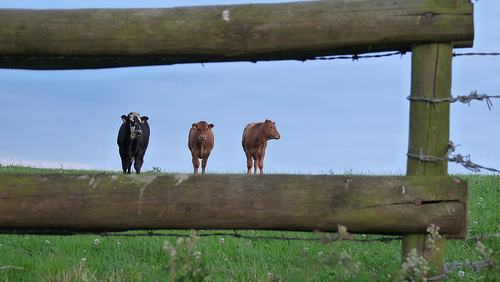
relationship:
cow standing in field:
[241, 118, 280, 175] [3, 110, 427, 275]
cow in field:
[116, 111, 151, 175] [33, 82, 499, 267]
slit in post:
[390, 190, 460, 209] [5, 165, 468, 234]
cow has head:
[116, 111, 151, 175] [122, 110, 150, 140]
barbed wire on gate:
[166, 37, 420, 67] [7, 3, 480, 264]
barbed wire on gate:
[86, 225, 406, 244] [7, 3, 480, 264]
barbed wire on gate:
[448, 46, 498, 57] [7, 3, 480, 264]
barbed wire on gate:
[406, 87, 498, 105] [7, 3, 480, 264]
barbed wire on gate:
[405, 149, 499, 177] [7, 3, 480, 264]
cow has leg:
[186, 120, 215, 175] [199, 154, 209, 174]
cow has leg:
[186, 120, 215, 175] [190, 154, 200, 173]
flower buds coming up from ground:
[1, 174, 499, 280] [0, 164, 498, 281]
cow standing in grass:
[116, 111, 151, 175] [0, 166, 499, 280]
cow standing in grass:
[186, 120, 215, 175] [0, 166, 499, 280]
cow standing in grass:
[241, 118, 280, 175] [0, 166, 499, 280]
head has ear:
[191, 120, 215, 141] [191, 122, 199, 132]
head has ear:
[191, 120, 215, 141] [207, 124, 214, 131]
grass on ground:
[0, 166, 499, 280] [0, 164, 498, 281]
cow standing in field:
[241, 118, 280, 175] [0, 163, 499, 282]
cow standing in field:
[114, 108, 150, 171] [0, 163, 499, 282]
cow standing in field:
[186, 120, 215, 175] [0, 163, 499, 282]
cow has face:
[116, 111, 151, 175] [126, 114, 143, 136]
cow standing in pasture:
[241, 118, 280, 175] [7, 236, 403, 280]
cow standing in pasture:
[186, 120, 215, 175] [7, 236, 403, 280]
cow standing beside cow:
[186, 120, 215, 175] [243, 116, 283, 172]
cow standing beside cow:
[186, 120, 215, 175] [114, 108, 150, 171]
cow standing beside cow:
[114, 111, 169, 178] [187, 120, 227, 174]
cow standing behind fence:
[116, 111, 151, 175] [6, 8, 495, 233]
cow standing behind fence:
[186, 120, 215, 175] [6, 8, 495, 233]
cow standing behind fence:
[241, 118, 280, 175] [6, 8, 495, 233]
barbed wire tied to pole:
[448, 51, 500, 58] [397, 43, 457, 191]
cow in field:
[241, 114, 281, 177] [2, 165, 498, 272]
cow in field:
[186, 120, 215, 175] [2, 165, 498, 272]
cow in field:
[116, 111, 151, 175] [2, 165, 498, 272]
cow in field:
[241, 118, 280, 175] [2, 165, 498, 272]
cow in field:
[186, 120, 215, 175] [112, 237, 229, 269]